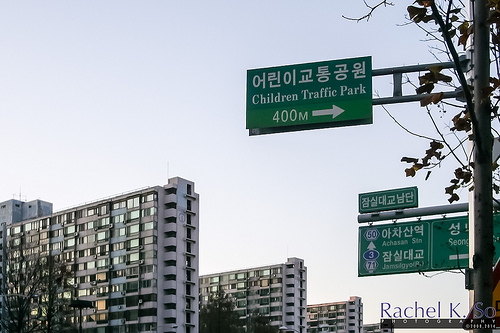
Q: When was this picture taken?
A: During the day.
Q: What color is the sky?
A: Blue.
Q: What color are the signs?
A: Green.